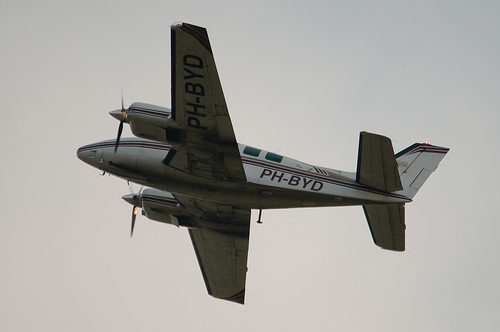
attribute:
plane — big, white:
[73, 15, 451, 310]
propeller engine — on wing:
[105, 86, 168, 152]